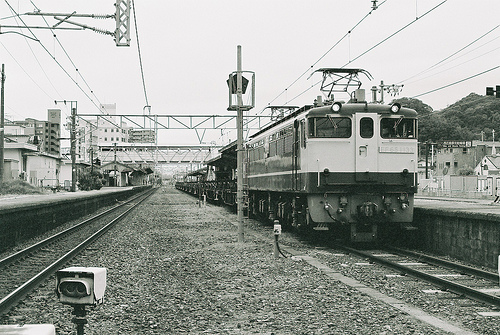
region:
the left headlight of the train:
[392, 100, 399, 110]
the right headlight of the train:
[327, 100, 337, 106]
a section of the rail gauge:
[374, 257, 403, 269]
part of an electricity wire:
[132, 41, 148, 99]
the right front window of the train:
[310, 114, 352, 137]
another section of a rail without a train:
[35, 225, 110, 267]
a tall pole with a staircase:
[231, 117, 251, 240]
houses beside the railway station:
[27, 137, 85, 181]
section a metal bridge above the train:
[133, 144, 197, 161]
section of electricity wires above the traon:
[293, 44, 390, 63]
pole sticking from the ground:
[265, 218, 302, 273]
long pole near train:
[215, 37, 255, 243]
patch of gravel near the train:
[139, 198, 219, 298]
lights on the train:
[316, 93, 415, 123]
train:
[163, 94, 443, 241]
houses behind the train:
[431, 131, 498, 193]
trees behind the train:
[391, 87, 498, 132]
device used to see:
[52, 258, 119, 333]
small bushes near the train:
[76, 168, 110, 191]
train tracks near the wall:
[364, 231, 498, 317]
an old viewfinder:
[51, 258, 108, 333]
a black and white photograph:
[3, 1, 498, 333]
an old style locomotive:
[248, 88, 418, 245]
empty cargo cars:
[168, 155, 238, 212]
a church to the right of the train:
[475, 127, 497, 197]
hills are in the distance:
[390, 89, 497, 150]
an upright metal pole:
[224, 44, 259, 246]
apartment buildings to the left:
[26, 119, 63, 156]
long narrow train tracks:
[3, 187, 161, 325]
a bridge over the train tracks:
[99, 142, 222, 167]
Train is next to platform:
[169, 65, 496, 275]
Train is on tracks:
[174, 68, 498, 309]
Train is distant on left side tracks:
[1, 158, 171, 333]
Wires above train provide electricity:
[1, 0, 498, 137]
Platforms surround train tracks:
[0, 179, 499, 334]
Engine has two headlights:
[240, 95, 421, 244]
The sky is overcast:
[0, 0, 499, 145]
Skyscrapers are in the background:
[10, 103, 163, 193]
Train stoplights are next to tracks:
[49, 38, 264, 332]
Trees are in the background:
[385, 80, 498, 155]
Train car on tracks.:
[172, 72, 478, 317]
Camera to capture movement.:
[53, 255, 111, 333]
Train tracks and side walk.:
[0, 181, 201, 258]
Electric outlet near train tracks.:
[266, 218, 288, 258]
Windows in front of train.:
[292, 113, 419, 140]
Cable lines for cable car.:
[1, 0, 498, 112]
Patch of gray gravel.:
[130, 262, 309, 327]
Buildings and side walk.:
[0, 113, 169, 192]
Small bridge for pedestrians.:
[77, 141, 227, 168]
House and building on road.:
[416, 133, 496, 218]